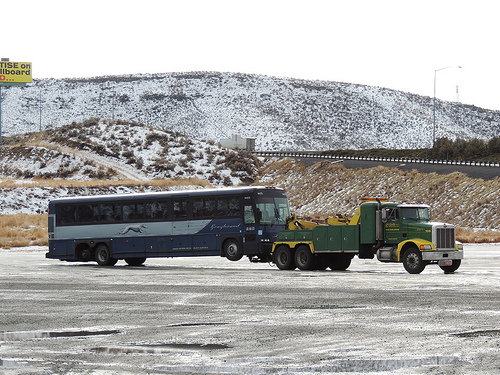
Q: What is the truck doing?
A: Pulling a bus.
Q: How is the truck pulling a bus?
A: With a pulley.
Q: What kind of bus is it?
A: Passenger bus.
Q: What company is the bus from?
A: Greyhound.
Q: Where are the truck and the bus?
A: Open parking lot.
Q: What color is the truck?
A: A lot of green and little yellow.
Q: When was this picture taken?
A: During the day.